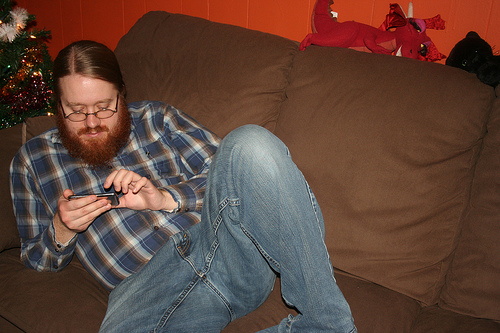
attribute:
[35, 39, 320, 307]
man — rough, scruffy, relaxing, resting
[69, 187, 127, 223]
cell phone — gray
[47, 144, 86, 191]
shirt — blue, plaid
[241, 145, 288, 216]
jeans — blue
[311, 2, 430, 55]
toy — red, dragon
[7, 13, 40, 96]
tree — green, decorated